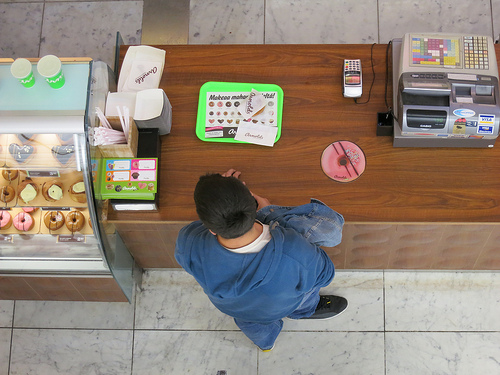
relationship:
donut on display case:
[10, 212, 38, 232] [0, 49, 131, 331]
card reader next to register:
[337, 53, 372, 103] [372, 25, 495, 156]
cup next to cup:
[9, 56, 37, 88] [36, 54, 64, 91]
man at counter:
[199, 190, 387, 347] [206, 24, 431, 238]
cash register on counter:
[386, 28, 499, 148] [106, 33, 496, 231]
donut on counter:
[0, 183, 14, 202] [0, 53, 140, 304]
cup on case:
[34, 52, 65, 92] [0, 55, 142, 307]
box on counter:
[99, 156, 158, 201] [106, 33, 496, 231]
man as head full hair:
[175, 165, 348, 350] [191, 172, 256, 238]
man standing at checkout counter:
[175, 165, 348, 350] [101, 38, 484, 269]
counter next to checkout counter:
[0, 53, 140, 304] [101, 38, 484, 269]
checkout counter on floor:
[101, 38, 484, 269] [371, 275, 439, 349]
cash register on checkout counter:
[376, 28, 499, 158] [101, 38, 500, 273]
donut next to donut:
[65, 208, 84, 230] [43, 208, 64, 229]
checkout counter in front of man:
[101, 38, 500, 273] [175, 165, 348, 350]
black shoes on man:
[281, 284, 369, 338] [175, 165, 348, 350]